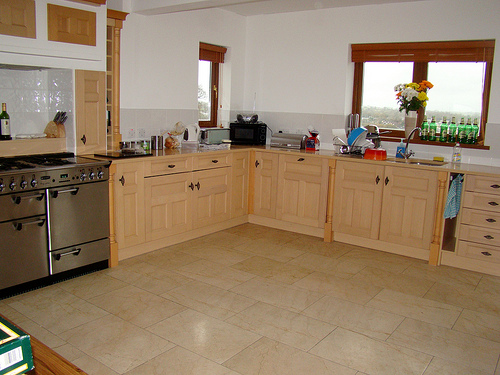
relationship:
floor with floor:
[0, 221, 499, 373] [0, 221, 499, 373]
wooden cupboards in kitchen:
[94, 142, 458, 262] [1, 1, 498, 373]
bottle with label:
[2, 101, 10, 137] [1, 119, 13, 134]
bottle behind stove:
[2, 101, 10, 137] [1, 150, 115, 299]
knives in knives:
[51, 103, 70, 133] [43, 111, 68, 138]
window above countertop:
[348, 39, 491, 150] [121, 132, 484, 177]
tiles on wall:
[16, 82, 42, 117] [143, 52, 188, 103]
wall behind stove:
[143, 52, 188, 103] [3, 155, 109, 272]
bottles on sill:
[417, 113, 478, 145] [354, 131, 485, 151]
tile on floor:
[308, 325, 434, 374] [0, 221, 499, 373]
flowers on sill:
[381, 73, 431, 137] [351, 127, 485, 153]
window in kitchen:
[344, 44, 499, 139] [1, 1, 498, 373]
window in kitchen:
[197, 57, 212, 120] [1, 1, 498, 373]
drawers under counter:
[449, 172, 499, 272] [248, 127, 484, 179]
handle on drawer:
[481, 251, 493, 258] [456, 240, 498, 265]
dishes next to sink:
[328, 122, 384, 162] [391, 125, 444, 169]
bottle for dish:
[439, 124, 464, 175] [433, 154, 447, 164]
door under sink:
[336, 163, 381, 236] [384, 124, 444, 166]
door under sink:
[383, 166, 435, 245] [384, 124, 444, 166]